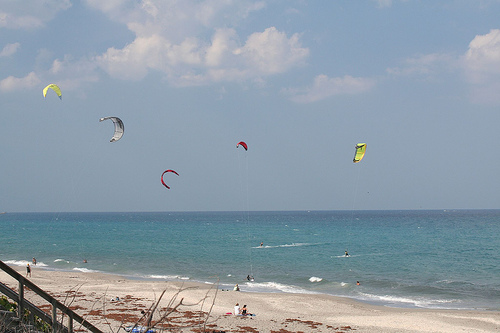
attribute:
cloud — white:
[93, 27, 302, 96]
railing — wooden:
[6, 253, 109, 331]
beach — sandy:
[4, 262, 498, 331]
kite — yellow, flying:
[339, 134, 392, 180]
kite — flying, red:
[218, 130, 246, 149]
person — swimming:
[327, 267, 379, 299]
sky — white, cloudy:
[37, 22, 477, 135]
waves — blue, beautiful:
[32, 204, 472, 299]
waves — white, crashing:
[65, 232, 304, 330]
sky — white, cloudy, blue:
[58, 39, 448, 186]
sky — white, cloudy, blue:
[67, 33, 433, 141]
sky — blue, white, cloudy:
[42, 24, 385, 154]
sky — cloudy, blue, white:
[75, 69, 465, 227]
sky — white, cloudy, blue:
[222, 19, 461, 175]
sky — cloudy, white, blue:
[26, 79, 466, 261]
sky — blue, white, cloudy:
[37, 55, 483, 235]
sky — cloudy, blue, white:
[7, 11, 488, 240]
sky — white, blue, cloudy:
[35, 43, 495, 207]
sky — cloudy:
[7, 35, 349, 243]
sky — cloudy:
[37, 62, 447, 204]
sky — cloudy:
[80, 38, 425, 147]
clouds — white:
[122, 20, 333, 81]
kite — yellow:
[38, 78, 66, 101]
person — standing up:
[237, 297, 255, 327]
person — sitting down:
[234, 280, 243, 294]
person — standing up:
[24, 263, 34, 279]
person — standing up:
[29, 253, 42, 264]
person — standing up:
[246, 265, 254, 281]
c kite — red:
[232, 138, 251, 154]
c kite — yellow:
[352, 138, 372, 170]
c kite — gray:
[102, 111, 132, 145]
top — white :
[232, 305, 243, 315]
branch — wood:
[129, 280, 196, 330]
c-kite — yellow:
[147, 161, 185, 194]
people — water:
[254, 227, 377, 266]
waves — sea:
[225, 229, 337, 255]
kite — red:
[227, 134, 257, 160]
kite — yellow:
[344, 135, 385, 168]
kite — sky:
[205, 125, 277, 162]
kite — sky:
[336, 138, 384, 167]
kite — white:
[85, 105, 134, 157]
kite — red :
[222, 140, 278, 163]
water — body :
[20, 214, 478, 287]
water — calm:
[88, 215, 482, 272]